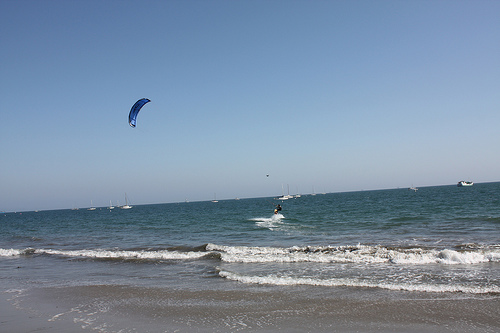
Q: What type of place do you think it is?
A: It is an ocean.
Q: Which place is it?
A: It is an ocean.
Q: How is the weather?
A: It is clear.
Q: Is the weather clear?
A: Yes, it is clear.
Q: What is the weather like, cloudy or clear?
A: It is clear.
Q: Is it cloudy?
A: No, it is clear.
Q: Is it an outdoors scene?
A: Yes, it is outdoors.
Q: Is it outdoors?
A: Yes, it is outdoors.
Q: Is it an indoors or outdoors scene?
A: It is outdoors.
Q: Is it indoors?
A: No, it is outdoors.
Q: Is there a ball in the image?
A: No, there are no balls.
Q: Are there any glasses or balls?
A: No, there are no balls or glasses.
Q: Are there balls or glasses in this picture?
A: No, there are no balls or glasses.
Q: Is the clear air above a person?
A: Yes, the air is above a person.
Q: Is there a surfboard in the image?
A: No, there are no surfboards.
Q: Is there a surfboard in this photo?
A: No, there are no surfboards.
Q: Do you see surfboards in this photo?
A: No, there are no surfboards.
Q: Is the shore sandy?
A: Yes, the shore is sandy.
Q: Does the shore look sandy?
A: Yes, the shore is sandy.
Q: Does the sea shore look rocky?
A: No, the sea shore is sandy.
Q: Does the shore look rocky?
A: No, the shore is sandy.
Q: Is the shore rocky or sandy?
A: The shore is sandy.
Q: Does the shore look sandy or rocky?
A: The shore is sandy.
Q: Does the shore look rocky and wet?
A: No, the shore is wet but sandy.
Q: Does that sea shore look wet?
A: Yes, the sea shore is wet.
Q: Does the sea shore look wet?
A: Yes, the sea shore is wet.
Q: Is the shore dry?
A: No, the shore is wet.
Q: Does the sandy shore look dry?
A: No, the shore is wet.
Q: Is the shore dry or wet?
A: The shore is wet.